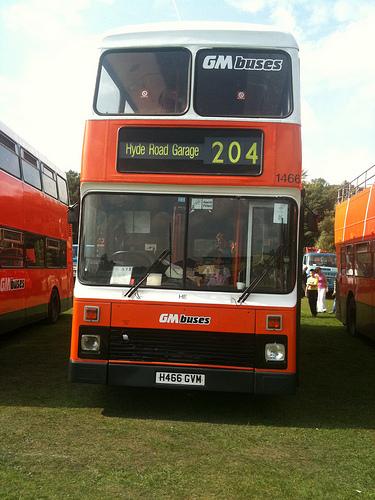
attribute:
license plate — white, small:
[150, 367, 208, 390]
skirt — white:
[316, 285, 328, 317]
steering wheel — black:
[109, 243, 151, 271]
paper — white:
[267, 200, 293, 227]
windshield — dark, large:
[75, 189, 302, 299]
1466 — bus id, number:
[274, 169, 303, 190]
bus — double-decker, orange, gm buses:
[62, 25, 311, 406]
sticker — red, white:
[236, 89, 247, 105]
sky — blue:
[2, 1, 371, 189]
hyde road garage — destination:
[116, 140, 207, 164]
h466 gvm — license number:
[159, 374, 200, 384]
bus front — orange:
[73, 299, 298, 383]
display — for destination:
[114, 124, 265, 177]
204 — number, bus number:
[207, 140, 261, 169]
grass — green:
[2, 291, 374, 499]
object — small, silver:
[119, 333, 133, 343]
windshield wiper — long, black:
[123, 245, 172, 303]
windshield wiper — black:
[235, 248, 286, 307]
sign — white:
[104, 262, 135, 291]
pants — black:
[303, 289, 318, 317]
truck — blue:
[301, 246, 340, 289]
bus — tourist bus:
[329, 159, 374, 352]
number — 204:
[202, 134, 263, 167]